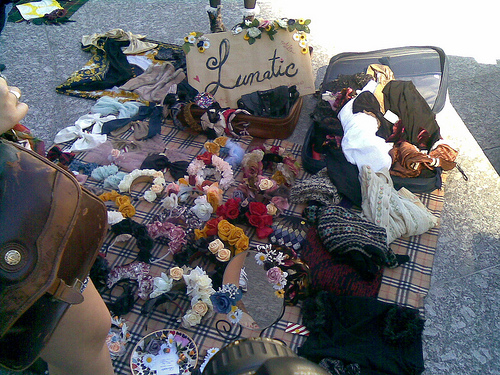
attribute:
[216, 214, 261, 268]
roses — red, orange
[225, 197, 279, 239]
roses — red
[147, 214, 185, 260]
roses — pink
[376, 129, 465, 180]
scarf — multi color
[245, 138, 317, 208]
headband — flowered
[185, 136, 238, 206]
headband — flowered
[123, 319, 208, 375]
plate — flower design, decorative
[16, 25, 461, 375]
blanket — checkered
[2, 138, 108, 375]
bag — leather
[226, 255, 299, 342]
mirror — round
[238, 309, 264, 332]
toes — reflection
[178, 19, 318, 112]
sign — cursive, writing, cardboard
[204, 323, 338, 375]
boots — pair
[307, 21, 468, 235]
suitcase — clothes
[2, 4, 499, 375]
ground — paved, grey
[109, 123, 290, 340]
flowers — colors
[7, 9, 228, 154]
sidewalk — ground, paved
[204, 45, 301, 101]
word — lunatic